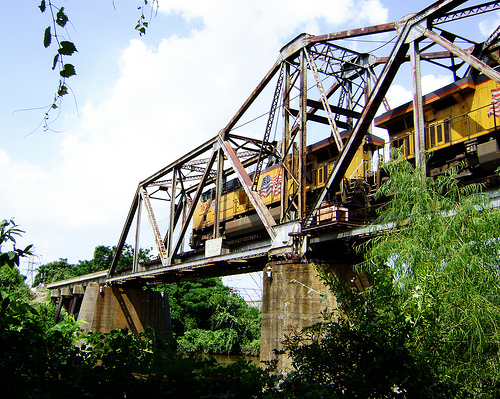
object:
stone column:
[66, 285, 175, 360]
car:
[188, 128, 385, 251]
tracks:
[103, 195, 500, 283]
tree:
[351, 143, 498, 398]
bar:
[106, 185, 139, 279]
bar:
[167, 166, 177, 265]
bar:
[213, 148, 225, 240]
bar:
[279, 61, 290, 224]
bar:
[409, 41, 427, 214]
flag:
[258, 174, 282, 199]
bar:
[140, 187, 167, 266]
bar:
[132, 187, 143, 274]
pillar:
[260, 259, 394, 398]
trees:
[278, 254, 499, 398]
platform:
[301, 221, 364, 237]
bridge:
[0, 0, 499, 393]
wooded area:
[30, 244, 262, 355]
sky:
[0, 0, 497, 314]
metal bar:
[304, 45, 345, 153]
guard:
[316, 206, 348, 226]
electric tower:
[21, 245, 44, 289]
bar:
[169, 149, 218, 264]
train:
[188, 63, 499, 250]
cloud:
[0, 0, 391, 313]